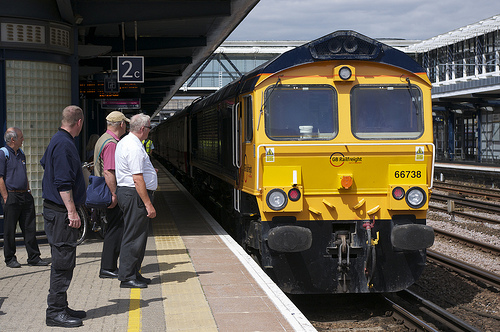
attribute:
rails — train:
[378, 236, 484, 327]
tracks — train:
[417, 241, 483, 330]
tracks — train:
[418, 187, 484, 254]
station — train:
[25, 21, 484, 320]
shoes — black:
[48, 300, 91, 328]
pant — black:
[37, 204, 83, 306]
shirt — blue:
[45, 136, 87, 209]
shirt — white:
[121, 129, 158, 191]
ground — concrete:
[5, 132, 263, 331]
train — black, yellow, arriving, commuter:
[152, 28, 440, 299]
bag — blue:
[85, 174, 110, 207]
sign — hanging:
[116, 56, 145, 83]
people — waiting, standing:
[0, 105, 170, 328]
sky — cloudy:
[181, 5, 483, 105]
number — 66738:
[394, 165, 423, 179]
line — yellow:
[111, 274, 145, 332]